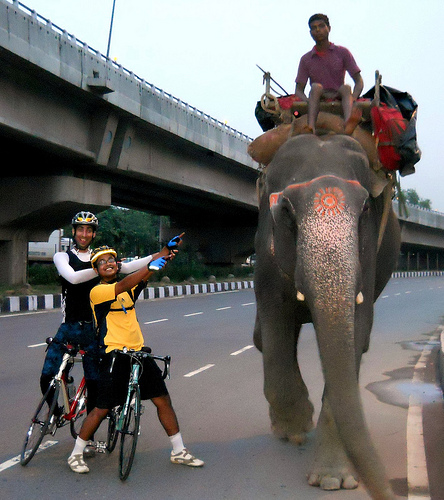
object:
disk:
[312, 186, 348, 219]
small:
[312, 184, 347, 219]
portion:
[165, 309, 229, 390]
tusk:
[355, 290, 365, 304]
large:
[293, 292, 307, 304]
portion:
[156, 145, 223, 223]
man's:
[64, 229, 205, 475]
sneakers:
[66, 452, 90, 474]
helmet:
[72, 211, 99, 226]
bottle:
[99, 358, 102, 361]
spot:
[366, 366, 443, 411]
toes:
[340, 472, 362, 491]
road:
[0, 268, 444, 500]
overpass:
[0, 0, 444, 268]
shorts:
[92, 349, 167, 409]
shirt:
[90, 282, 149, 354]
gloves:
[148, 255, 169, 274]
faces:
[71, 224, 96, 248]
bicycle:
[19, 334, 104, 467]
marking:
[312, 183, 345, 218]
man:
[293, 12, 364, 136]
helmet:
[90, 244, 118, 268]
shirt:
[52, 246, 153, 283]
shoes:
[169, 448, 205, 469]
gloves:
[165, 235, 184, 251]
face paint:
[302, 184, 362, 311]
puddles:
[365, 329, 444, 410]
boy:
[39, 212, 179, 459]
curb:
[0, 280, 254, 322]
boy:
[65, 230, 205, 473]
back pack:
[369, 101, 411, 173]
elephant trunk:
[297, 216, 399, 500]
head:
[261, 132, 383, 290]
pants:
[39, 320, 100, 412]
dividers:
[143, 318, 170, 326]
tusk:
[294, 289, 306, 301]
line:
[404, 342, 430, 499]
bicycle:
[93, 344, 172, 483]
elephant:
[249, 130, 411, 500]